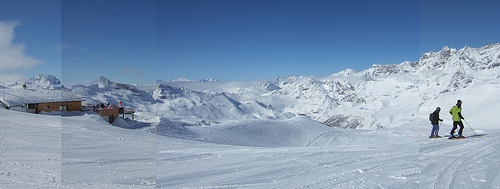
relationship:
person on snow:
[426, 104, 446, 143] [1, 111, 500, 187]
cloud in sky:
[2, 9, 48, 86] [2, 2, 500, 84]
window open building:
[57, 104, 69, 114] [1, 91, 121, 121]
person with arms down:
[426, 104, 446, 143] [429, 111, 443, 125]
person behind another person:
[426, 104, 446, 143] [446, 96, 467, 143]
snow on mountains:
[1, 111, 500, 187] [1, 42, 500, 129]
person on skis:
[446, 96, 467, 143] [445, 136, 473, 142]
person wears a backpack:
[426, 104, 446, 143] [430, 112, 437, 125]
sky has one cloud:
[2, 2, 500, 84] [2, 9, 48, 86]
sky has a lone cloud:
[2, 2, 500, 84] [2, 9, 48, 86]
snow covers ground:
[1, 111, 500, 187] [2, 128, 498, 189]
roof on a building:
[15, 91, 125, 107] [1, 91, 121, 121]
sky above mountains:
[2, 2, 500, 84] [1, 42, 500, 129]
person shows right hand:
[426, 104, 446, 143] [435, 116, 443, 123]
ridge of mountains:
[3, 44, 500, 87] [1, 42, 500, 129]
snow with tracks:
[1, 111, 500, 187] [143, 141, 498, 189]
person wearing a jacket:
[426, 104, 446, 143] [431, 113, 442, 133]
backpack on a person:
[430, 112, 437, 125] [426, 104, 446, 143]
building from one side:
[1, 91, 121, 121] [23, 102, 88, 114]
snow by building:
[1, 111, 500, 187] [1, 91, 121, 121]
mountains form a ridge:
[1, 42, 500, 129] [3, 44, 500, 87]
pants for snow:
[432, 125, 441, 142] [1, 111, 500, 187]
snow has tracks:
[1, 111, 500, 187] [143, 141, 498, 189]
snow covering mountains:
[1, 111, 500, 187] [1, 42, 500, 129]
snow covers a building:
[1, 111, 500, 187] [1, 91, 121, 121]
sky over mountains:
[2, 2, 500, 84] [1, 42, 500, 129]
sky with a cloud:
[2, 2, 500, 84] [2, 9, 48, 86]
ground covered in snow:
[2, 128, 498, 189] [1, 111, 500, 187]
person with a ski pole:
[446, 96, 467, 143] [463, 115, 475, 137]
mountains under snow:
[1, 42, 500, 129] [1, 111, 500, 187]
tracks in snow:
[143, 141, 498, 189] [1, 111, 500, 187]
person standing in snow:
[426, 104, 446, 143] [1, 111, 500, 187]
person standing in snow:
[446, 96, 467, 143] [1, 111, 500, 187]